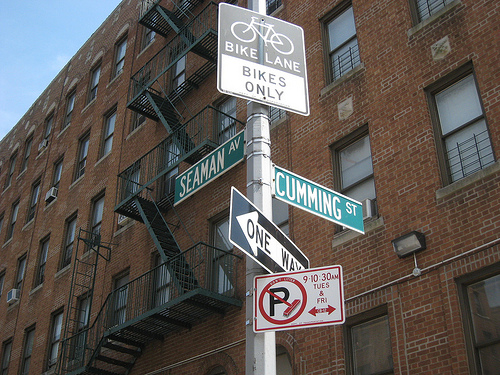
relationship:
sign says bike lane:
[219, 1, 311, 117] [224, 41, 301, 73]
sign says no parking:
[253, 264, 348, 333] [260, 274, 307, 326]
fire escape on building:
[58, 1, 246, 374] [1, 1, 499, 371]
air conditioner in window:
[44, 187, 56, 200] [49, 161, 62, 198]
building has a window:
[1, 1, 499, 371] [49, 161, 62, 198]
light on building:
[390, 231, 426, 260] [1, 1, 499, 371]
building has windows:
[1, 1, 499, 371] [1, 1, 499, 374]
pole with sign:
[244, 2, 277, 374] [253, 264, 348, 333]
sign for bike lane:
[219, 1, 311, 117] [224, 41, 301, 73]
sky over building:
[0, 0, 123, 142] [1, 1, 499, 371]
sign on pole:
[219, 1, 311, 117] [244, 2, 277, 374]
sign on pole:
[227, 184, 310, 274] [244, 2, 277, 374]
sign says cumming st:
[274, 162, 365, 234] [275, 171, 357, 223]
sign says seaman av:
[172, 128, 246, 207] [178, 135, 244, 197]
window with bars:
[432, 72, 497, 182] [447, 125, 497, 181]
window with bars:
[325, 8, 368, 81] [328, 43, 361, 82]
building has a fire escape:
[1, 1, 499, 371] [58, 1, 246, 374]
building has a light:
[1, 1, 499, 371] [390, 231, 426, 260]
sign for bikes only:
[219, 1, 311, 117] [240, 64, 285, 101]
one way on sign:
[246, 217, 304, 271] [227, 184, 310, 274]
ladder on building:
[57, 230, 100, 372] [1, 1, 499, 371]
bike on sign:
[231, 14, 294, 56] [219, 1, 311, 117]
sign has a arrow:
[227, 184, 310, 274] [235, 207, 304, 269]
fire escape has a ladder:
[58, 1, 246, 374] [57, 230, 100, 372]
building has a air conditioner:
[1, 1, 499, 371] [44, 187, 56, 200]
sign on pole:
[253, 264, 348, 333] [244, 2, 277, 374]